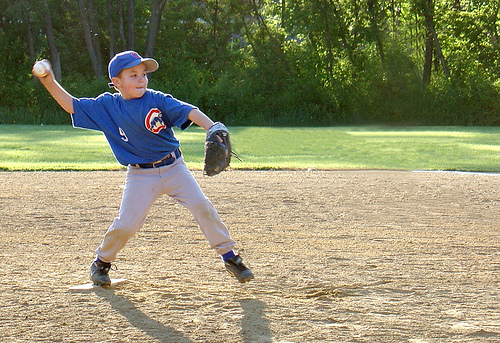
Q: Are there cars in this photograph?
A: No, there are no cars.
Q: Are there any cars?
A: No, there are no cars.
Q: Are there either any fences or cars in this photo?
A: No, there are no cars or fences.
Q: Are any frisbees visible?
A: No, there are no frisbees.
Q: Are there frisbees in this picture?
A: No, there are no frisbees.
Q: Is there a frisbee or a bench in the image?
A: No, there are no frisbees or benches.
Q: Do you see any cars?
A: No, there are no cars.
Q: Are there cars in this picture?
A: No, there are no cars.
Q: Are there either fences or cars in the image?
A: No, there are no cars or fences.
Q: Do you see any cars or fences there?
A: No, there are no cars or fences.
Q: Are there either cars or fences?
A: No, there are no cars or fences.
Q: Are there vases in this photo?
A: No, there are no vases.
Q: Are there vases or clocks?
A: No, there are no vases or clocks.